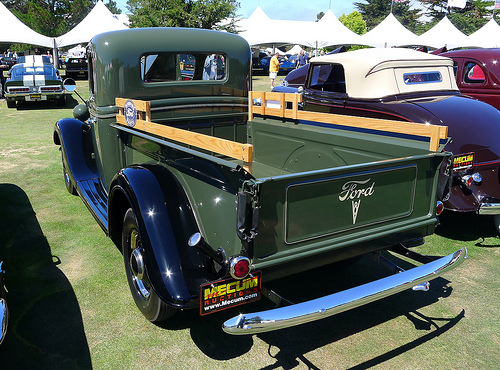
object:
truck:
[46, 25, 456, 329]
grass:
[42, 212, 119, 348]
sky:
[282, 5, 309, 17]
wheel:
[116, 202, 181, 329]